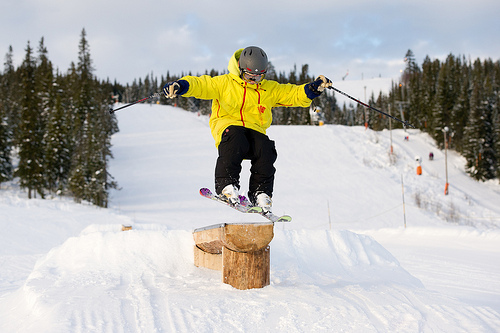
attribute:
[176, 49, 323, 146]
coat — yellow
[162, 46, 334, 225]
skier — jumping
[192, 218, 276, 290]
bench — wood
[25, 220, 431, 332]
hill — snow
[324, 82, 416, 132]
ski pole — black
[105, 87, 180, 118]
ski pole — black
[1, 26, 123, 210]
pine tree — evergreen, tall, green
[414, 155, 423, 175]
object — orange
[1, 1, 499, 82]
sky — cloudy, grey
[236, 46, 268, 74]
helmet — beige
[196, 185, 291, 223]
skis — purple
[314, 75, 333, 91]
glove — black, yellow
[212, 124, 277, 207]
pants — black, warm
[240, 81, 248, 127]
line — red